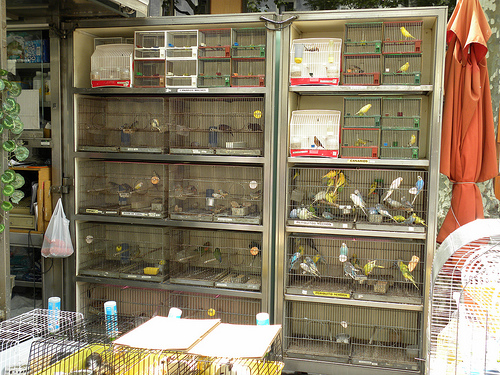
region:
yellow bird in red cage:
[382, 22, 422, 54]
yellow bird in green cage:
[382, 52, 425, 84]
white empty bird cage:
[165, 32, 205, 84]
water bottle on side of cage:
[45, 296, 69, 333]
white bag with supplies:
[39, 189, 74, 272]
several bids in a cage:
[286, 232, 426, 314]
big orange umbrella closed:
[442, 2, 489, 239]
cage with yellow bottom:
[55, 307, 287, 373]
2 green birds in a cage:
[172, 231, 262, 285]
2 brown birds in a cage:
[169, 99, 274, 152]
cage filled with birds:
[291, 168, 423, 235]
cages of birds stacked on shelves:
[283, 21, 421, 373]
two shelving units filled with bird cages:
[65, 23, 420, 373]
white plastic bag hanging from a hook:
[29, 191, 86, 275]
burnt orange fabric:
[440, 3, 499, 242]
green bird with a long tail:
[391, 257, 421, 293]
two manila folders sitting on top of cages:
[116, 304, 278, 371]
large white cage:
[426, 227, 499, 367]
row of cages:
[7, 295, 293, 372]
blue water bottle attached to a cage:
[37, 291, 64, 337]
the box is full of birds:
[246, 154, 457, 281]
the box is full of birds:
[319, 170, 490, 248]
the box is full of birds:
[270, 91, 425, 241]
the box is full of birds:
[187, 70, 421, 324]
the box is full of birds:
[293, 124, 395, 265]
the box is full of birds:
[287, 135, 417, 349]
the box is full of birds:
[330, 117, 408, 287]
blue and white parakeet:
[327, 238, 354, 270]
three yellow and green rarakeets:
[304, 170, 354, 208]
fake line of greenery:
[1, 89, 24, 239]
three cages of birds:
[292, 168, 407, 371]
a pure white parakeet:
[375, 173, 403, 205]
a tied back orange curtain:
[420, 94, 492, 275]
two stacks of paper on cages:
[110, 302, 285, 364]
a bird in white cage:
[283, 102, 342, 176]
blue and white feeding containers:
[86, 289, 132, 351]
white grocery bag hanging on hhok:
[33, 185, 81, 274]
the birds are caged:
[153, 113, 365, 368]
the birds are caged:
[174, 130, 290, 337]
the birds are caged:
[277, 101, 470, 371]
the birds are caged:
[346, 103, 417, 365]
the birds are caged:
[298, 76, 394, 367]